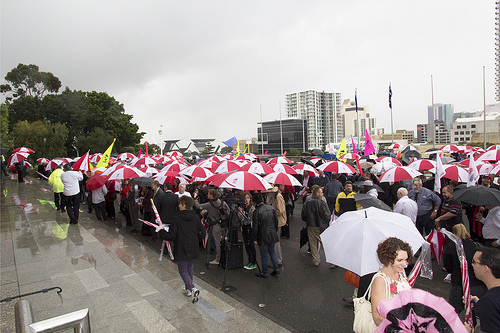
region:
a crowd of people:
[19, 92, 499, 324]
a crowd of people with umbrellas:
[30, 95, 464, 331]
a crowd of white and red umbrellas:
[21, 103, 491, 265]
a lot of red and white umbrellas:
[42, 109, 474, 274]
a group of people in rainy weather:
[35, 87, 497, 265]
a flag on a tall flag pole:
[344, 57, 421, 167]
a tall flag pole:
[366, 79, 400, 155]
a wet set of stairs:
[14, 181, 215, 331]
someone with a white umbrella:
[314, 180, 457, 288]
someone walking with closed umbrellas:
[79, 157, 235, 312]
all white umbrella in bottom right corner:
[308, 195, 423, 285]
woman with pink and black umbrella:
[357, 221, 417, 331]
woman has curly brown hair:
[375, 237, 418, 269]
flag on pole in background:
[369, 74, 405, 131]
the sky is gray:
[11, 6, 489, 123]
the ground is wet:
[5, 175, 227, 330]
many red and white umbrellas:
[59, 147, 456, 195]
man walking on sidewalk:
[59, 159, 97, 234]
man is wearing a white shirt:
[57, 170, 91, 193]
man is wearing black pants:
[59, 190, 94, 231]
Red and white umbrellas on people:
[61, 153, 329, 226]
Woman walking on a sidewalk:
[171, 189, 228, 304]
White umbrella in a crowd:
[313, 192, 418, 282]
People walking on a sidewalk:
[48, 153, 106, 220]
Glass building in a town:
[248, 105, 327, 175]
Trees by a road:
[15, 71, 162, 176]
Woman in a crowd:
[356, 240, 437, 331]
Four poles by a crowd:
[346, 76, 498, 153]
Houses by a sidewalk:
[162, 121, 269, 178]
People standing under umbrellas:
[169, 181, 292, 278]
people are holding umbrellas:
[39, 126, 411, 207]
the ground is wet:
[47, 229, 171, 326]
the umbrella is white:
[307, 212, 432, 278]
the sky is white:
[117, 21, 307, 97]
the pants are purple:
[150, 249, 217, 299]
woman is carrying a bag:
[337, 216, 409, 328]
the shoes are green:
[236, 253, 270, 279]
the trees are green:
[33, 83, 133, 143]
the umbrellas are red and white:
[113, 141, 280, 221]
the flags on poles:
[331, 71, 428, 131]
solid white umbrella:
[317, 199, 429, 286]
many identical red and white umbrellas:
[2, 144, 497, 198]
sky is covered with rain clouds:
[2, 5, 497, 145]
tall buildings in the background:
[253, 87, 453, 142]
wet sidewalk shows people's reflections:
[4, 174, 135, 265]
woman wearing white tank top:
[357, 230, 412, 331]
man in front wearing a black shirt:
[468, 241, 499, 331]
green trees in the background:
[0, 60, 165, 163]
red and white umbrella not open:
[425, 217, 443, 272]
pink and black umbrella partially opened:
[368, 287, 470, 326]